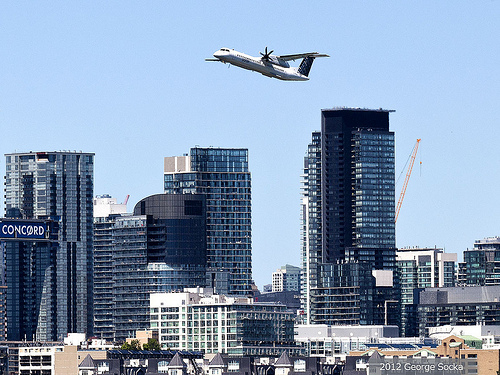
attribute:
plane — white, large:
[220, 33, 321, 83]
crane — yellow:
[395, 143, 429, 214]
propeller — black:
[252, 47, 274, 69]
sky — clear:
[37, 14, 161, 79]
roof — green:
[454, 329, 481, 341]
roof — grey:
[422, 289, 499, 304]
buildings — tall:
[10, 111, 395, 334]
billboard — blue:
[0, 216, 57, 242]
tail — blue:
[297, 59, 312, 73]